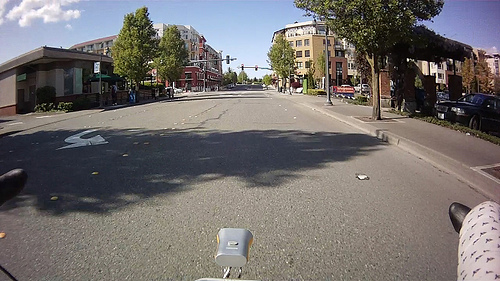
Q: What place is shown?
A: It is a street.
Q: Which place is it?
A: It is a street.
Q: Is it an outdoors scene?
A: Yes, it is outdoors.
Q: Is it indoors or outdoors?
A: It is outdoors.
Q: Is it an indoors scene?
A: No, it is outdoors.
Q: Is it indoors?
A: No, it is outdoors.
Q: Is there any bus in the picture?
A: No, there are no buses.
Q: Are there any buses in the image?
A: No, there are no buses.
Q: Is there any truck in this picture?
A: Yes, there is a truck.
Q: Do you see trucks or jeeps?
A: Yes, there is a truck.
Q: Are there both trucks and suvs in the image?
A: No, there is a truck but no suvs.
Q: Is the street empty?
A: Yes, the street is empty.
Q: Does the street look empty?
A: Yes, the street is empty.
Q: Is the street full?
A: No, the street is empty.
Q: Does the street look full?
A: No, the street is empty.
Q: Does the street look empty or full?
A: The street is empty.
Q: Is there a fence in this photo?
A: No, there are no fences.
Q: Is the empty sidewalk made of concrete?
A: Yes, the sidewalk is made of concrete.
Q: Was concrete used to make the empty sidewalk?
A: Yes, the sidewalk is made of concrete.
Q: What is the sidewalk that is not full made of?
A: The sidewalk is made of cement.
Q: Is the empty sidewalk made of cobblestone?
A: No, the sidewalk is made of concrete.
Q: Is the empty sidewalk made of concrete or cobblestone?
A: The side walk is made of concrete.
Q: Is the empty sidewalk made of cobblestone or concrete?
A: The side walk is made of concrete.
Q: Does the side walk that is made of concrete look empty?
A: Yes, the sidewalk is empty.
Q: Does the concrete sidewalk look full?
A: No, the sidewalk is empty.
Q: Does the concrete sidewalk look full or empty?
A: The sidewalk is empty.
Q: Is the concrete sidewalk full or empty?
A: The sidewalk is empty.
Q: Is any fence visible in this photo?
A: No, there are no fences.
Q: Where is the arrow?
A: The arrow is on the street.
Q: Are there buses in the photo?
A: No, there are no buses.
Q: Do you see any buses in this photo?
A: No, there are no buses.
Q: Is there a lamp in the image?
A: Yes, there is a lamp.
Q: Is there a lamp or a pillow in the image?
A: Yes, there is a lamp.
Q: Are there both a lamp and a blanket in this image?
A: No, there is a lamp but no blankets.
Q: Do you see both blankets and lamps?
A: No, there is a lamp but no blankets.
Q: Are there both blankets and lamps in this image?
A: No, there is a lamp but no blankets.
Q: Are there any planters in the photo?
A: No, there are no planters.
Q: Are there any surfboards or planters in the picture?
A: No, there are no planters or surfboards.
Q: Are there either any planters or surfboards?
A: No, there are no planters or surfboards.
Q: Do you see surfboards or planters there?
A: No, there are no planters or surfboards.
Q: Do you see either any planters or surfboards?
A: No, there are no planters or surfboards.